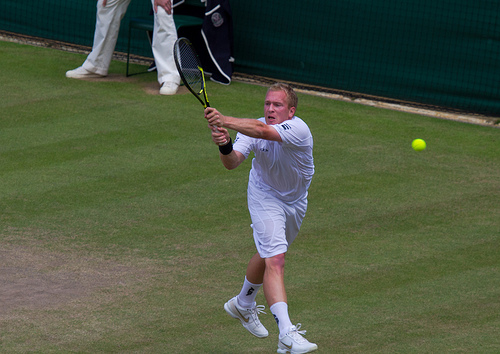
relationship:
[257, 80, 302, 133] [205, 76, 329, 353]
head of man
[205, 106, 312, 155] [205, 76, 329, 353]
arm of man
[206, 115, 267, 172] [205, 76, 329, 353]
arm of man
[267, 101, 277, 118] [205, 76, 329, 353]
nose of man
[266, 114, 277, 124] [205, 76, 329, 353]
mouth of man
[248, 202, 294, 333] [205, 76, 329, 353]
legs of man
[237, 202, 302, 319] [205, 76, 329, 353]
legs of man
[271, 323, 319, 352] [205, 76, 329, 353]
shoes of man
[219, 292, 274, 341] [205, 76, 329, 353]
shoes of man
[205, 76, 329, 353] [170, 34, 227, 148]
man swinging racket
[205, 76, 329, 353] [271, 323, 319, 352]
man wearing shoes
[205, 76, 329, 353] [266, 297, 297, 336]
man wearing socks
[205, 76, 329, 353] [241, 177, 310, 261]
man wearing shorts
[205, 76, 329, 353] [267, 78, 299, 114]
man has hair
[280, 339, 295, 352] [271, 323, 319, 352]
logo on shoes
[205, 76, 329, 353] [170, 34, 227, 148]
man holding racket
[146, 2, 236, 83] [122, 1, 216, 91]
jacket over chair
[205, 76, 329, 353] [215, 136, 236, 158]
man wearing wristband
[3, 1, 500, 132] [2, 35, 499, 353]
fence behind court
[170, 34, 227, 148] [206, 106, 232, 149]
racket in hands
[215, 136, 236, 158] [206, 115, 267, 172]
wristband on arm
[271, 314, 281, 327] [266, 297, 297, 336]
design on socks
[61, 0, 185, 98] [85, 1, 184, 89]
person wearing pants